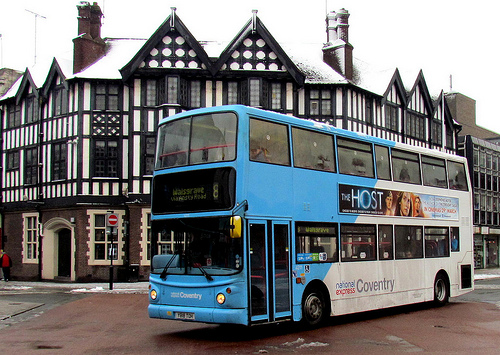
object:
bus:
[146, 104, 476, 335]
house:
[0, 0, 499, 293]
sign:
[105, 213, 123, 227]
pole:
[109, 226, 114, 290]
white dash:
[109, 218, 117, 222]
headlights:
[215, 292, 226, 305]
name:
[335, 277, 395, 295]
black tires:
[300, 281, 330, 329]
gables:
[135, 3, 214, 79]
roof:
[0, 11, 499, 148]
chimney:
[72, 1, 105, 74]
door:
[248, 219, 292, 326]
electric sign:
[170, 184, 220, 202]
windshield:
[151, 215, 244, 275]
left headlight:
[149, 289, 157, 300]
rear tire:
[434, 273, 450, 307]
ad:
[337, 181, 461, 222]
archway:
[38, 217, 77, 282]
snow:
[75, 38, 147, 80]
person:
[0, 248, 13, 282]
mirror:
[230, 215, 243, 239]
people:
[314, 152, 333, 171]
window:
[249, 116, 292, 167]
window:
[53, 84, 69, 116]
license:
[174, 311, 195, 320]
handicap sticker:
[304, 265, 310, 274]